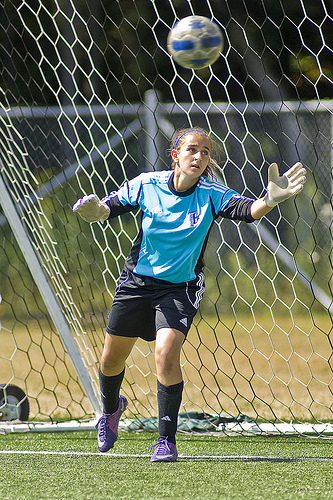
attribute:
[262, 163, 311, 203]
gloves — white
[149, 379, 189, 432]
sock — black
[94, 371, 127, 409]
sock — black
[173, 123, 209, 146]
headband — blue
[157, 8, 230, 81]
ball — white, blue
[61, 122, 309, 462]
woman — playing soccer, standing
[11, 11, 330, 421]
net — white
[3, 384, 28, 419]
wheel — black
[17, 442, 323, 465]
line — white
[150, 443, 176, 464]
shoe — purple, pink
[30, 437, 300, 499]
grass — green, fresh, short, viewable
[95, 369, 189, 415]
socks — black, dark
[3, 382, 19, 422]
tire — silver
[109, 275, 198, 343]
shorts — black